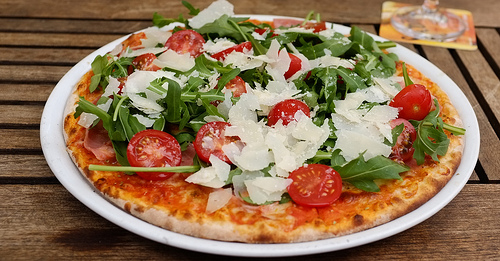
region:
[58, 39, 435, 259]
pizza on a plate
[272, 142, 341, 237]
tomato slice on pizza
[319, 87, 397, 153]
sliced cheese on pizza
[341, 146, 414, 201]
dandelion greens on pizza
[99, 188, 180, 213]
melted cheese on pizza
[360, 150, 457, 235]
brown crust of pizza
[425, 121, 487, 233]
plate rim above table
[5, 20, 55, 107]
planks of the wooden table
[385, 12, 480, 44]
base of glass on table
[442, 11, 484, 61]
coaster under the glass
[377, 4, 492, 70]
bottom of a wine glass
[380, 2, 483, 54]
an orange cardboard coaster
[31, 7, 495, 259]
a pizza on a white plate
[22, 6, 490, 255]
a pizza on a wooden table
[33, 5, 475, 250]
a pizza with tomatoes, greens, and cheese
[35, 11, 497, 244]
a small pizza with grated cheese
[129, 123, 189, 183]
a half of a red tomato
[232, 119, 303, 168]
fresh shredded cheese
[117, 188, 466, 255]
golden pizza crust with sauce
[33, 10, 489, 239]
a pizza with fresh vegetable toppings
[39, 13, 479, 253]
Whole pizza on a plate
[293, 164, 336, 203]
Uncooked cherry tomato slices on pizza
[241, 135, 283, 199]
Parmesan cheese flakes on pizza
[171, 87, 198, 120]
Uncooked arugula on pizza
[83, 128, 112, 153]
Ham slices on pizza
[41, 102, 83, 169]
White plate holding pizza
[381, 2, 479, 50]
Paper coaster under glass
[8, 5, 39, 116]
Wooden slats tabletop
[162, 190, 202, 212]
Golden cheese on pizza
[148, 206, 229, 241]
Thin pizza crust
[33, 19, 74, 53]
dark colored wood plank table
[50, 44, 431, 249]
white ceramic plate for pizza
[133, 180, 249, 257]
cheese pizza underneath vegetables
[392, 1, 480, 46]
orange coaster under glass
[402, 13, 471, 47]
bottom base of wine glass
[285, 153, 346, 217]
pieces of small tomoates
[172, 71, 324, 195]
shreddings of parmesan cheese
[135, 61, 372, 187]
leaves of basil on pizza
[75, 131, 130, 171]
sice of ham in pizza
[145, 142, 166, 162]
inside seeds of tomatoe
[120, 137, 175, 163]
red tomatoes is on the top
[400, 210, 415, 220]
edge of plate is white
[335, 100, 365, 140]
cheese is cut very fine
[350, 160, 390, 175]
green leaf is very healhy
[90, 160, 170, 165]
stem is very long and thin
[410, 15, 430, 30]
bottom of the glass is round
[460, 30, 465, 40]
coaster is on the table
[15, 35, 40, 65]
table is made of wood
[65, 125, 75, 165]
crust is very thin and little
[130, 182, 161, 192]
sauce on the pizza is red